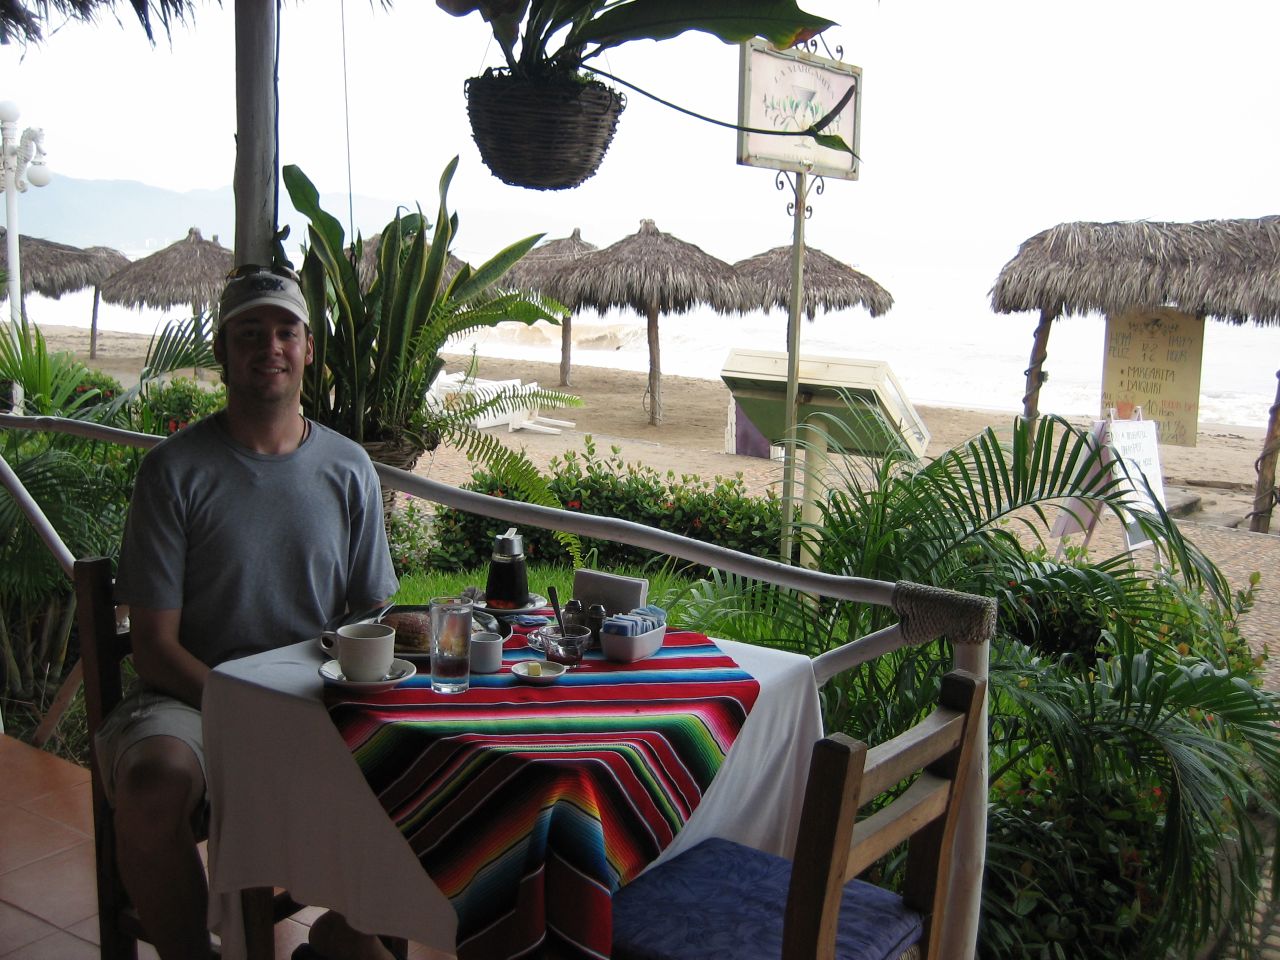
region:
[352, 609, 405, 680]
cup is white in color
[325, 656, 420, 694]
saucer is white in color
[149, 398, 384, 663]
man is wearing shirt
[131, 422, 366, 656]
shirt is grey in color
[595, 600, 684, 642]
sugar packets are blue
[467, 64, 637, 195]
planter hanging from the ceiling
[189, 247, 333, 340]
man is wearing a hat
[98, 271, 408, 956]
man sitting at a table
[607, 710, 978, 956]
empty chair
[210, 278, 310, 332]
baseball cap on the man's head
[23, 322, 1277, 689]
a sandy beach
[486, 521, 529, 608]
maple syrup in a dispenser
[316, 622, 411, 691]
coffee cup on a saucer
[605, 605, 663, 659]
sugar packets in a container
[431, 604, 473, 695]
a tall glass of water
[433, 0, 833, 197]
hanging basket with a green plant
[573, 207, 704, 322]
straw roof on the log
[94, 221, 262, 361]
straw roof on the log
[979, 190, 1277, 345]
straw roof on the log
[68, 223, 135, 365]
straw roof on the log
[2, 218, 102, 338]
straw roof on the log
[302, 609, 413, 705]
Coffee mug on the table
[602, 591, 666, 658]
sugar packets in the bowl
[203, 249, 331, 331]
man wearing a hat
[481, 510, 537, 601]
jar of syrup on the table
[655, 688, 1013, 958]
wooden chair in front of table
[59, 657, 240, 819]
man wearing brown shorts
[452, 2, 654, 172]
plant hanging over the man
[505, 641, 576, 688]
quarter square of butter in dish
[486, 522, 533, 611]
thick brown syrup in glass container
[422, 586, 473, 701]
mostly empty glass of water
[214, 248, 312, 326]
sunglasses perched on top of white baseball cap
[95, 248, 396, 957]
smiling man in shorts and grey shirt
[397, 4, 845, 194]
leafy green plant in weaved basket hanging from rafters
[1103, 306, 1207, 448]
faded yellowish sign listing beverage prices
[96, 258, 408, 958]
man sitting a table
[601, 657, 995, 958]
an empty chair with a blue seat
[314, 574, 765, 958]
a brightly colored cloth on the table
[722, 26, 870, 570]
a rectangular sign on a tall pole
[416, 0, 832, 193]
hanging plant in a basket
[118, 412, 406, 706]
gray, short-sleeved t-shirt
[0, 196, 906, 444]
round, stationary umbrellas on the beach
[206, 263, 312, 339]
baseball style cap on the man's head